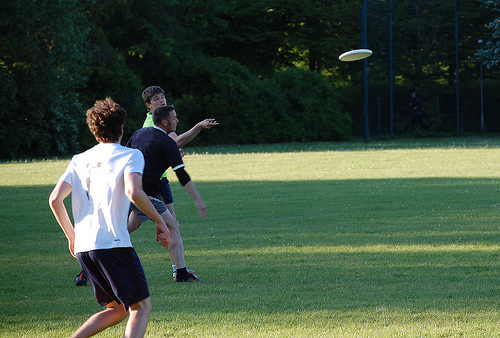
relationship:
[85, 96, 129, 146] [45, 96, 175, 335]
head of man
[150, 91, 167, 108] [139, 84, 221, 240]
face of person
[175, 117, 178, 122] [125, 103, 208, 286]
nose of guy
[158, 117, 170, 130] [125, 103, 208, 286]
ear of guy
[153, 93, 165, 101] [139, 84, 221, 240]
eyes of person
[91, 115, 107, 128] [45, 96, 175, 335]
hair of man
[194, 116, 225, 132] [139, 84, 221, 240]
hand of person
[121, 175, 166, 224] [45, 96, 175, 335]
arm of man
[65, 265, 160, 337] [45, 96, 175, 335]
legs of man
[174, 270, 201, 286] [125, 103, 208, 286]
foot of guy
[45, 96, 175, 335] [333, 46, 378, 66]
man playing frisbee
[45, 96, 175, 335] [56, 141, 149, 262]
man wearing shirt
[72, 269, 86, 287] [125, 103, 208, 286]
shoe of guy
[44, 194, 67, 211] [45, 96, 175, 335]
left elbow of man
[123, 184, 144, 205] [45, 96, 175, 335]
right elbow of man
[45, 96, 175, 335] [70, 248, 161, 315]
man wearing shorts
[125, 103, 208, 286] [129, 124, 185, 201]
guy wearing shirt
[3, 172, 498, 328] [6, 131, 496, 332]
shadow on field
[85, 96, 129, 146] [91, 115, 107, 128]
head has hair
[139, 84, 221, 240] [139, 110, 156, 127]
person wearing shirt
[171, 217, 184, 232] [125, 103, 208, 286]
right knee of guy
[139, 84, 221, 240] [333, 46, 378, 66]
person playing frisbee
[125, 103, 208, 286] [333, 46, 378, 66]
guy playing frisbee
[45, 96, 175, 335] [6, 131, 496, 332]
man in field